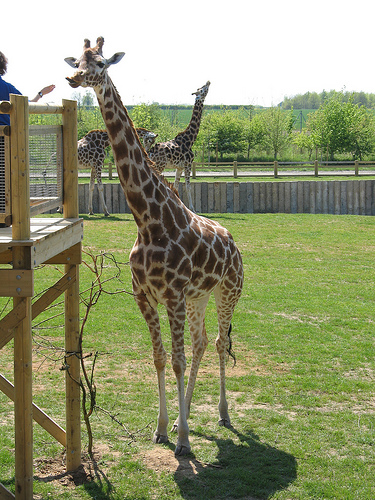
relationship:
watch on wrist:
[36, 90, 44, 98] [36, 89, 44, 99]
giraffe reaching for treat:
[63, 34, 244, 458] [48, 83, 54, 88]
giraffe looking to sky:
[140, 74, 213, 178] [4, 3, 363, 107]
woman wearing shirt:
[0, 50, 56, 228] [2, 80, 25, 126]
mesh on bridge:
[27, 125, 63, 208] [1, 90, 84, 497]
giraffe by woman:
[63, 34, 244, 458] [0, 50, 56, 228]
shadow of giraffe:
[162, 424, 298, 499] [63, 34, 244, 458]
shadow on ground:
[162, 424, 298, 499] [0, 212, 363, 490]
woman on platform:
[0, 50, 56, 228] [3, 88, 84, 494]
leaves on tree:
[319, 107, 354, 132] [291, 94, 363, 164]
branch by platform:
[66, 249, 128, 467] [3, 88, 84, 494]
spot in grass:
[136, 443, 199, 479] [3, 211, 363, 497]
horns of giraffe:
[83, 35, 104, 49] [63, 34, 244, 458]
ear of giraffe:
[95, 35, 105, 50] [63, 34, 244, 458]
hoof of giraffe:
[172, 441, 191, 458] [63, 34, 244, 458]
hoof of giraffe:
[154, 428, 172, 447] [63, 34, 244, 458]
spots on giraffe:
[148, 205, 199, 284] [63, 34, 244, 458]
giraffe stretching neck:
[140, 74, 213, 178] [183, 100, 206, 140]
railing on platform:
[5, 90, 84, 237] [3, 88, 84, 494]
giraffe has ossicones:
[63, 34, 244, 458] [81, 32, 103, 50]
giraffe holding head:
[140, 76, 207, 180] [191, 77, 212, 106]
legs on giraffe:
[128, 252, 239, 456] [63, 34, 244, 458]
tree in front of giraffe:
[60, 243, 135, 487] [63, 34, 244, 458]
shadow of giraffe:
[157, 424, 295, 495] [63, 34, 244, 458]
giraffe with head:
[40, 125, 157, 219] [143, 132, 157, 153]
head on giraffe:
[143, 132, 157, 153] [140, 74, 213, 178]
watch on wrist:
[35, 90, 43, 98] [36, 89, 44, 99]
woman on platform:
[3, 51, 54, 237] [3, 88, 84, 494]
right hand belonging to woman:
[40, 83, 55, 96] [0, 50, 56, 228]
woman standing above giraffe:
[0, 50, 56, 228] [63, 34, 244, 458]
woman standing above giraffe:
[0, 50, 56, 228] [40, 125, 157, 219]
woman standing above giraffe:
[0, 50, 56, 228] [140, 74, 213, 178]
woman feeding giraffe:
[0, 50, 56, 228] [63, 34, 244, 458]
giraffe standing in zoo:
[63, 34, 244, 458] [1, 93, 363, 497]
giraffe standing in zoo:
[40, 125, 157, 219] [1, 93, 363, 497]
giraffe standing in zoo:
[140, 74, 213, 178] [1, 93, 363, 497]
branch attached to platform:
[66, 249, 128, 467] [3, 88, 84, 494]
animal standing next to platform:
[63, 35, 245, 457] [3, 88, 84, 494]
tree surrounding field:
[199, 104, 249, 159] [24, 108, 363, 171]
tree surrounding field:
[249, 100, 300, 160] [24, 108, 363, 171]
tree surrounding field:
[308, 87, 363, 162] [24, 108, 363, 171]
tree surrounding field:
[130, 100, 155, 136] [24, 108, 363, 171]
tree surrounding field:
[81, 88, 95, 109] [24, 108, 363, 171]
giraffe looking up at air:
[140, 74, 213, 178] [2, 2, 363, 108]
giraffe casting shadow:
[63, 34, 244, 458] [162, 424, 298, 499]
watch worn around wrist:
[37, 90, 43, 98] [36, 89, 44, 99]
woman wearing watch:
[0, 50, 56, 228] [37, 90, 43, 98]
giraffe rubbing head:
[40, 125, 157, 219] [143, 132, 157, 153]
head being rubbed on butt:
[143, 132, 157, 153] [146, 142, 162, 163]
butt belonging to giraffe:
[146, 142, 162, 163] [140, 74, 213, 178]